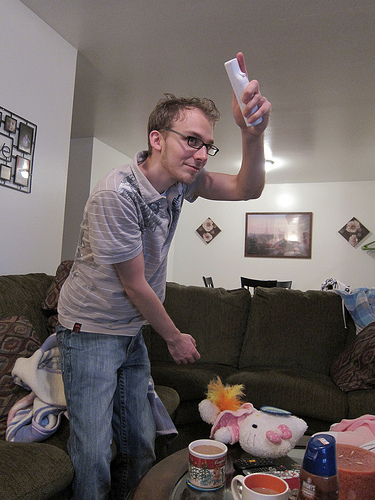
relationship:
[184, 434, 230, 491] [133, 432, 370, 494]
mug on table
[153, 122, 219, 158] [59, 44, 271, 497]
eyeglasses on man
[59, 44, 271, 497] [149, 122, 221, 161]
man wearing eyeglasses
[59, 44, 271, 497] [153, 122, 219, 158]
man wearing eyeglasses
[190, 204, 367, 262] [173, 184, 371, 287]
pictures on wall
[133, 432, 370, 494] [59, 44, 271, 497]
table in front of man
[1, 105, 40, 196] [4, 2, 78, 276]
picture on wall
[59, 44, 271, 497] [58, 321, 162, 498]
man wearing jeans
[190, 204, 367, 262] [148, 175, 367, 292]
pictures are on a wall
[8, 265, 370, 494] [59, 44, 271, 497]
couch behind man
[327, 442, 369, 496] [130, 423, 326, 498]
candle on table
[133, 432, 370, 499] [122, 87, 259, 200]
table in front of man